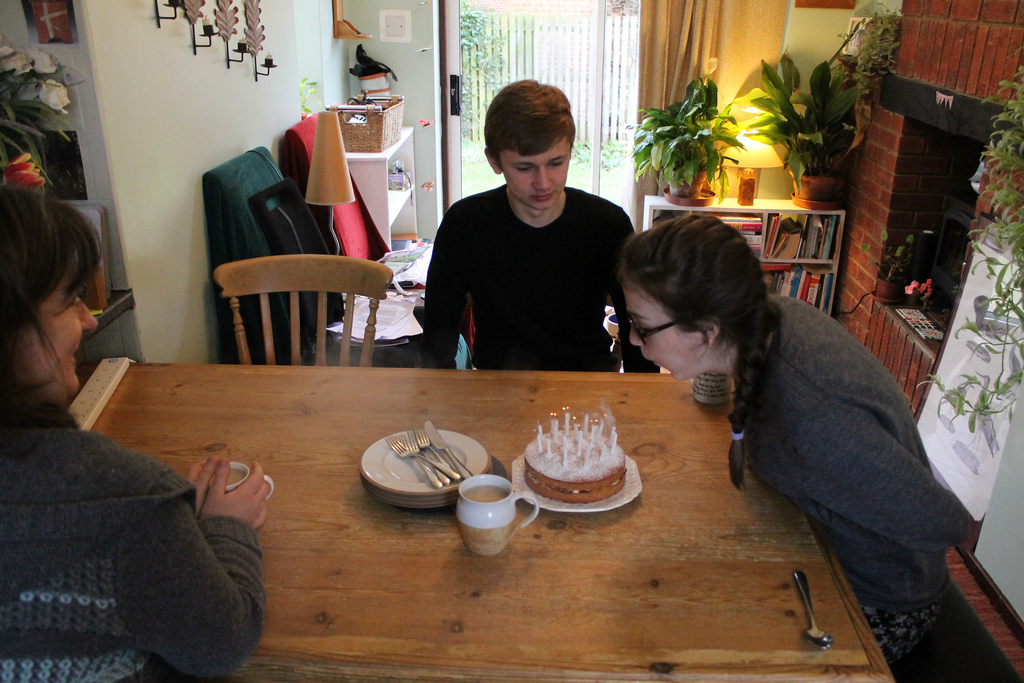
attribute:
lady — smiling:
[600, 173, 832, 554]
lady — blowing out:
[598, 167, 841, 530]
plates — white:
[331, 377, 532, 525]